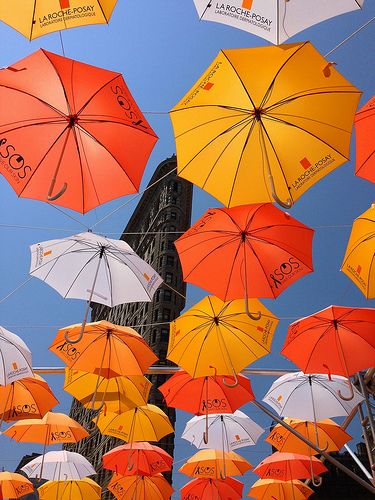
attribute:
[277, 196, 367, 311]
sky — blue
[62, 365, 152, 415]
umbrella — orange , yellow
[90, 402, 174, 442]
umbrella — yellow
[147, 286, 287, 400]
umbrella — yellow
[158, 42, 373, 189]
umbrella — white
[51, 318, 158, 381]
orange umbrella — light orange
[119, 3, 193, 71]
bright sky — cloudless, blue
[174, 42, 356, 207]
umbrellas — yellow 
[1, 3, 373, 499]
umbrellas — numerous, white, orange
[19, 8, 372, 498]
picture — taken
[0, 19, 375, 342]
wires — suspending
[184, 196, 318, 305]
umbrella — orange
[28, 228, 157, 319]
white umbrella — large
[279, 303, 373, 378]
umbrella — orange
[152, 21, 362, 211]
umbrella — large, white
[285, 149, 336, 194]
logo — red 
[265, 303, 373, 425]
umbrellas — suspended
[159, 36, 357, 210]
umbrella — yellow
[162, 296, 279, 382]
umbrella — yellow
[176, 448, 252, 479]
umbrella — yellow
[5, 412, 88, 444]
umbrella — yellow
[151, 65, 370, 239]
umbrella — light orange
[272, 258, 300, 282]
lettering — black 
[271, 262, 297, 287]
awareness — black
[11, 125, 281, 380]
cables — gray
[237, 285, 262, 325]
handle — gray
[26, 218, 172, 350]
umbrella — white, orange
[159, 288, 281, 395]
umbrella — large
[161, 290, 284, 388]
umbrella — yellow, red